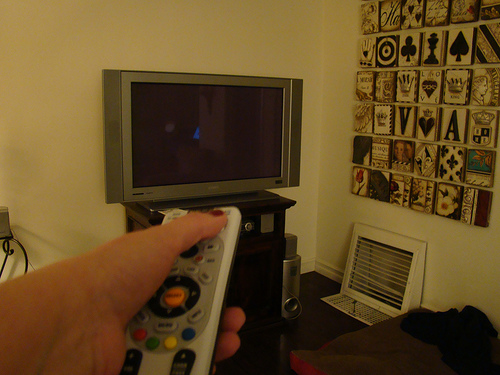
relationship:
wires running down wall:
[1, 236, 28, 282] [0, 0, 320, 280]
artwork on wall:
[348, 0, 499, 228] [314, 0, 499, 332]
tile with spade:
[442, 25, 474, 65] [448, 30, 469, 65]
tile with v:
[391, 102, 417, 141] [398, 105, 410, 132]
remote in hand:
[119, 193, 246, 373] [2, 200, 228, 372]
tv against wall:
[109, 75, 299, 184] [7, 6, 336, 236]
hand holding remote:
[2, 200, 228, 372] [119, 193, 246, 373]